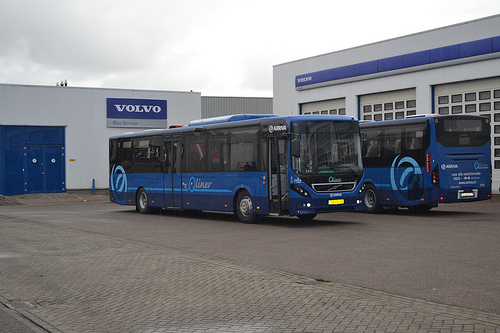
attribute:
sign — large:
[105, 92, 169, 128]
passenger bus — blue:
[368, 112, 495, 207]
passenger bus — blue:
[109, 112, 364, 222]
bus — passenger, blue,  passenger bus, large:
[112, 110, 373, 226]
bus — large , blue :
[144, 99, 498, 203]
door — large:
[431, 71, 498, 194]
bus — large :
[108, 107, 374, 239]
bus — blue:
[354, 115, 498, 215]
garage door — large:
[352, 87, 424, 124]